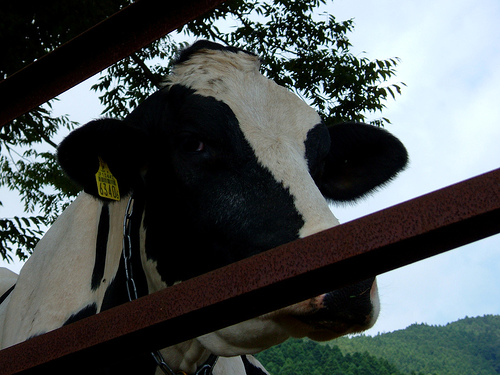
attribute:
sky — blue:
[353, 2, 495, 172]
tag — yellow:
[99, 162, 119, 205]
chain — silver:
[120, 194, 138, 303]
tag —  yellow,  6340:
[94, 162, 121, 200]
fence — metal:
[1, 175, 488, 364]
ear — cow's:
[58, 114, 133, 201]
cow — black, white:
[0, 39, 416, 372]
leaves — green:
[87, 0, 409, 130]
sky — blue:
[1, 0, 499, 341]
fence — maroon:
[2, 2, 499, 374]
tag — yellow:
[93, 163, 123, 203]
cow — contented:
[20, 44, 391, 346]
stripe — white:
[195, 51, 342, 232]